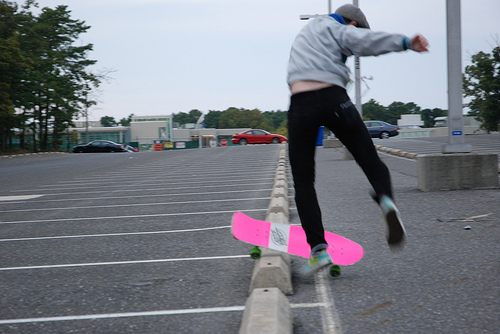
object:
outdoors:
[0, 0, 500, 334]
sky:
[72, 0, 500, 121]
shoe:
[300, 250, 333, 278]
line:
[0, 197, 271, 213]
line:
[11, 182, 273, 192]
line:
[0, 225, 231, 242]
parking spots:
[0, 146, 277, 334]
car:
[72, 139, 127, 153]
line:
[0, 254, 251, 270]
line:
[0, 302, 326, 326]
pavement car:
[232, 129, 288, 146]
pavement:
[0, 144, 278, 334]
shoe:
[378, 197, 405, 243]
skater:
[287, 3, 429, 280]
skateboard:
[230, 210, 363, 277]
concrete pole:
[442, 0, 472, 153]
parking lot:
[0, 143, 500, 334]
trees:
[170, 97, 453, 137]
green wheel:
[250, 247, 262, 259]